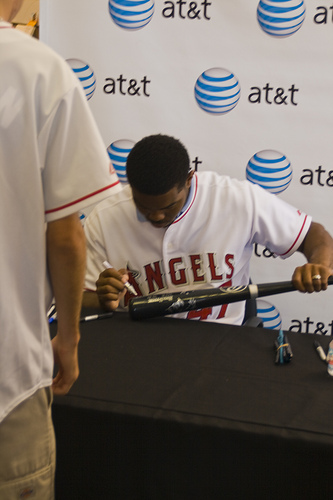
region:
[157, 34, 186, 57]
part of a banner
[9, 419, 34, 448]
part of a trouser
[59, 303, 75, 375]
edge of a hand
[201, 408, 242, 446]
part of a cloth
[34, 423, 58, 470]
edge of a trouser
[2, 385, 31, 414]
edge of a shirt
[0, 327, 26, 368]
part of a shirt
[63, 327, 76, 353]
edge of a hand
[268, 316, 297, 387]
part of some pens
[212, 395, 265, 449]
edge of a stage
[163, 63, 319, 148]
At&T logo at the wall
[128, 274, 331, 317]
a black metal baseball bat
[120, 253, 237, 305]
the Angels baseball logo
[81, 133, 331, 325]
a baseball player signing a bat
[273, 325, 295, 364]
pens with a rubberband around them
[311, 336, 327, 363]
a black colored sharpie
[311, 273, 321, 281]
a baseball player's ring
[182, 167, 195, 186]
a black man's left ear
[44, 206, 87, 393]
a white man's skinny arm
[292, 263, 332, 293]
a man's left hand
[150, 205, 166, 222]
a baseball player's nose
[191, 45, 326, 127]
the background is at&t logos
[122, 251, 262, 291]
ANGELS is on the front of the jersey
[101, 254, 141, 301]
the marker is white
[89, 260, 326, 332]
the bat is black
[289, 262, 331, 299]
wedding ring on his hand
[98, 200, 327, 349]
jersey is white and red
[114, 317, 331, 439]
top of the table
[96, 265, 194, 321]
player signing the bat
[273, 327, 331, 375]
marker/pens on the table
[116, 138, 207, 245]
player looking at the bat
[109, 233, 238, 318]
red writing on white jersey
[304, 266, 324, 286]
ring on left hand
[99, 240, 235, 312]
the word Angels on jersey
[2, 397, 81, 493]
shorts of a person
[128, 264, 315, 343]
black bat in man's hand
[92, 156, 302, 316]
man signing a bat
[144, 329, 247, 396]
black table under man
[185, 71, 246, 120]
blue and white ball logo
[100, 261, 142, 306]
pen in man's hand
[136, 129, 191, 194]
black hair on man's head